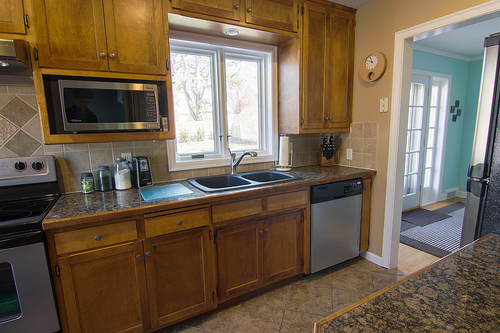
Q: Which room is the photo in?
A: It is at the kitchen.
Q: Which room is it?
A: It is a kitchen.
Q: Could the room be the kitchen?
A: Yes, it is the kitchen.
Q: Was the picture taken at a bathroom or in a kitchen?
A: It was taken at a kitchen.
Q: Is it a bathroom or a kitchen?
A: It is a kitchen.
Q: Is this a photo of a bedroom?
A: No, the picture is showing a kitchen.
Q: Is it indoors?
A: Yes, it is indoors.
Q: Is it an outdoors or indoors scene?
A: It is indoors.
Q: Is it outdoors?
A: No, it is indoors.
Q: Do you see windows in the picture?
A: Yes, there is a window.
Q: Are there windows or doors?
A: Yes, there is a window.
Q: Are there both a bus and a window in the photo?
A: No, there is a window but no buses.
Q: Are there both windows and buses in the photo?
A: No, there is a window but no buses.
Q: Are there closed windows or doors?
A: Yes, there is a closed window.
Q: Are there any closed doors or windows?
A: Yes, there is a closed window.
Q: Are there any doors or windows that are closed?
A: Yes, the window is closed.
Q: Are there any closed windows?
A: Yes, there is a closed window.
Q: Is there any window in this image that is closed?
A: Yes, there is a closed window.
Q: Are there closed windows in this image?
A: Yes, there is a closed window.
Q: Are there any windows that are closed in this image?
A: Yes, there is a closed window.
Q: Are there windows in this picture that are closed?
A: Yes, there is a window that is closed.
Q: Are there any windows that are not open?
A: Yes, there is an closed window.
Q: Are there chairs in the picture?
A: No, there are no chairs.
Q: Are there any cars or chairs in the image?
A: No, there are no chairs or cars.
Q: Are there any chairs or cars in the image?
A: No, there are no chairs or cars.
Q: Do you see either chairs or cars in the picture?
A: No, there are no chairs or cars.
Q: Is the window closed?
A: Yes, the window is closed.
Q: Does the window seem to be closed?
A: Yes, the window is closed.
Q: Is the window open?
A: No, the window is closed.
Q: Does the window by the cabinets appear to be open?
A: No, the window is closed.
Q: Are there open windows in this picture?
A: No, there is a window but it is closed.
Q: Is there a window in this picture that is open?
A: No, there is a window but it is closed.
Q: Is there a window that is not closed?
A: No, there is a window but it is closed.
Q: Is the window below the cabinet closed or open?
A: The window is closed.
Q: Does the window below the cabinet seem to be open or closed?
A: The window is closed.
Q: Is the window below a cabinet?
A: Yes, the window is below a cabinet.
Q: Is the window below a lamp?
A: No, the window is below a cabinet.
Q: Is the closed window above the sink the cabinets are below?
A: Yes, the window is above the sink.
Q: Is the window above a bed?
A: No, the window is above the sink.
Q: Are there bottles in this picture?
A: No, there are no bottles.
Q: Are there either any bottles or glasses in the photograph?
A: No, there are no bottles or glasses.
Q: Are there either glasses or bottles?
A: No, there are no bottles or glasses.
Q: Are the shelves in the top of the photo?
A: Yes, the shelves are in the top of the image.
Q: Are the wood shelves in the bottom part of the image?
A: No, the shelves are in the top of the image.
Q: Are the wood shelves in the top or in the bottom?
A: The shelves are in the top of the image.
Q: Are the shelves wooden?
A: Yes, the shelves are wooden.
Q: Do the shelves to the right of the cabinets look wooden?
A: Yes, the shelves are wooden.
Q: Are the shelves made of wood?
A: Yes, the shelves are made of wood.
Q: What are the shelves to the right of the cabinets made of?
A: The shelves are made of wood.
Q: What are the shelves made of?
A: The shelves are made of wood.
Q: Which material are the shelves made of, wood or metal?
A: The shelves are made of wood.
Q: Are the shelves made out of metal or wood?
A: The shelves are made of wood.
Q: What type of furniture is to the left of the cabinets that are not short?
A: The pieces of furniture are shelves.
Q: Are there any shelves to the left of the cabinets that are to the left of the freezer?
A: Yes, there are shelves to the left of the cabinets.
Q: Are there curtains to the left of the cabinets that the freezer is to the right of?
A: No, there are shelves to the left of the cabinets.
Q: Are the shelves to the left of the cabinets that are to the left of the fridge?
A: Yes, the shelves are to the left of the cabinets.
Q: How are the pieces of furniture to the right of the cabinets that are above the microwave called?
A: The pieces of furniture are shelves.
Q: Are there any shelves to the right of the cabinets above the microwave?
A: Yes, there are shelves to the right of the cabinets.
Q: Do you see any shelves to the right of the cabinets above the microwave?
A: Yes, there are shelves to the right of the cabinets.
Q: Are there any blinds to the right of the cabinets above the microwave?
A: No, there are shelves to the right of the cabinets.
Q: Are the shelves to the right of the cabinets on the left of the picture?
A: Yes, the shelves are to the right of the cabinets.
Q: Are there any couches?
A: No, there are no couches.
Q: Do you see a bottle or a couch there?
A: No, there are no couches or bottles.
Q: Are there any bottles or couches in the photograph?
A: No, there are no couches or bottles.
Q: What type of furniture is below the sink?
A: The pieces of furniture are cabinets.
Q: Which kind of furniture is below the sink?
A: The pieces of furniture are cabinets.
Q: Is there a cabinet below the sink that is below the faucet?
A: Yes, there are cabinets below the sink.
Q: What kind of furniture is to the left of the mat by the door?
A: The pieces of furniture are cabinets.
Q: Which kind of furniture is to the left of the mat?
A: The pieces of furniture are cabinets.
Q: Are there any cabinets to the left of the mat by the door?
A: Yes, there are cabinets to the left of the mat.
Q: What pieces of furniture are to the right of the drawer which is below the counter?
A: The pieces of furniture are cabinets.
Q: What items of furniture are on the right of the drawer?
A: The pieces of furniture are cabinets.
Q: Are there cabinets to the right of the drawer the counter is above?
A: Yes, there are cabinets to the right of the drawer.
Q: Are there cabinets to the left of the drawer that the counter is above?
A: No, the cabinets are to the right of the drawer.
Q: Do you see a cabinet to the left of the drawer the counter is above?
A: No, the cabinets are to the right of the drawer.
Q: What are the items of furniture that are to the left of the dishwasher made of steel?
A: The pieces of furniture are cabinets.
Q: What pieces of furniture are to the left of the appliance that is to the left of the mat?
A: The pieces of furniture are cabinets.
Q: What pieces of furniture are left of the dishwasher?
A: The pieces of furniture are cabinets.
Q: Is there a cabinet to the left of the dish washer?
A: Yes, there are cabinets to the left of the dish washer.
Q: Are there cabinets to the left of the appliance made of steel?
A: Yes, there are cabinets to the left of the dish washer.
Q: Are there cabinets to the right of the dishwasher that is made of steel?
A: No, the cabinets are to the left of the dish washer.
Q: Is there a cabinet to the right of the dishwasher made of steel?
A: No, the cabinets are to the left of the dish washer.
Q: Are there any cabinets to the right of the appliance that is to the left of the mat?
A: No, the cabinets are to the left of the dish washer.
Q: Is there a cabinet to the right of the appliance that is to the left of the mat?
A: No, the cabinets are to the left of the dish washer.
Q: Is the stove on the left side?
A: Yes, the stove is on the left of the image.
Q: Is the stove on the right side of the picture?
A: No, the stove is on the left of the image.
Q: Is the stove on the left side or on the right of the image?
A: The stove is on the left of the image.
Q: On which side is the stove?
A: The stove is on the left of the image.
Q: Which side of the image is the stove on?
A: The stove is on the left of the image.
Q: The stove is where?
A: The stove is in the kitchen.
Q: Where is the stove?
A: The stove is in the kitchen.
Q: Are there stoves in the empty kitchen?
A: Yes, there is a stove in the kitchen.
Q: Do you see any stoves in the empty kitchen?
A: Yes, there is a stove in the kitchen.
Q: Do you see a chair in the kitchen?
A: No, there is a stove in the kitchen.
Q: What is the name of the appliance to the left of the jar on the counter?
A: The appliance is a stove.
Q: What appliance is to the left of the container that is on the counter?
A: The appliance is a stove.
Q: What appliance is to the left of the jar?
A: The appliance is a stove.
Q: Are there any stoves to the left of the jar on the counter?
A: Yes, there is a stove to the left of the jar.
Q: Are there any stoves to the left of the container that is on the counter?
A: Yes, there is a stove to the left of the jar.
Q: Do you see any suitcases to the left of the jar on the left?
A: No, there is a stove to the left of the jar.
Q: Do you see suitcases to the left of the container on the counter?
A: No, there is a stove to the left of the jar.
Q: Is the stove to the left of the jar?
A: Yes, the stove is to the left of the jar.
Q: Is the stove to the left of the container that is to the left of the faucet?
A: Yes, the stove is to the left of the jar.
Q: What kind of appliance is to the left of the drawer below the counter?
A: The appliance is a stove.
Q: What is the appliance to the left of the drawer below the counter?
A: The appliance is a stove.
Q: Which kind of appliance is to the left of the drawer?
A: The appliance is a stove.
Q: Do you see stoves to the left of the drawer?
A: Yes, there is a stove to the left of the drawer.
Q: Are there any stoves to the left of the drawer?
A: Yes, there is a stove to the left of the drawer.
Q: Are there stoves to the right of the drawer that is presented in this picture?
A: No, the stove is to the left of the drawer.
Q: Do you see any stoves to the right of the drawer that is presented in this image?
A: No, the stove is to the left of the drawer.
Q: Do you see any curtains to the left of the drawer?
A: No, there is a stove to the left of the drawer.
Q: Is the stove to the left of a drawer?
A: Yes, the stove is to the left of a drawer.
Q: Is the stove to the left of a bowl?
A: No, the stove is to the left of a drawer.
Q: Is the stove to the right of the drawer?
A: No, the stove is to the left of the drawer.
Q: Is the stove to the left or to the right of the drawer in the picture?
A: The stove is to the left of the drawer.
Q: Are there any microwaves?
A: Yes, there is a microwave.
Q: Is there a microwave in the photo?
A: Yes, there is a microwave.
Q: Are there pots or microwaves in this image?
A: Yes, there is a microwave.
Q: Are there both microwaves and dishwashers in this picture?
A: Yes, there are both a microwave and a dishwasher.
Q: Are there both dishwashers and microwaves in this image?
A: Yes, there are both a microwave and a dishwasher.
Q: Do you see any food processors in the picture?
A: No, there are no food processors.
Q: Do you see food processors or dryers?
A: No, there are no food processors or dryers.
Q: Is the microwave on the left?
A: Yes, the microwave is on the left of the image.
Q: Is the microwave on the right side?
A: No, the microwave is on the left of the image.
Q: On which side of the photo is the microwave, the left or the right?
A: The microwave is on the left of the image.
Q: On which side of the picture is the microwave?
A: The microwave is on the left of the image.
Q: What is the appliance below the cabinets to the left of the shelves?
A: The appliance is a microwave.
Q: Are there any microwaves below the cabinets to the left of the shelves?
A: Yes, there is a microwave below the cabinets.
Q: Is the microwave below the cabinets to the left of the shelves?
A: Yes, the microwave is below the cabinets.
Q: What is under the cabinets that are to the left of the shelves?
A: The microwave is under the cabinets.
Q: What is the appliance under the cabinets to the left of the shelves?
A: The appliance is a microwave.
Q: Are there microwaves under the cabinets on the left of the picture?
A: Yes, there is a microwave under the cabinets.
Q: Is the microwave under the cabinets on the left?
A: Yes, the microwave is under the cabinets.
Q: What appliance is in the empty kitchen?
A: The appliance is a microwave.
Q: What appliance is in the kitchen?
A: The appliance is a microwave.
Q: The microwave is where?
A: The microwave is in the kitchen.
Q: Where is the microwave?
A: The microwave is in the kitchen.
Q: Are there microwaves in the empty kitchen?
A: Yes, there is a microwave in the kitchen.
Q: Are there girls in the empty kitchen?
A: No, there is a microwave in the kitchen.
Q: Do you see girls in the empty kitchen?
A: No, there is a microwave in the kitchen.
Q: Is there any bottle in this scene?
A: No, there are no bottles.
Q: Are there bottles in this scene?
A: No, there are no bottles.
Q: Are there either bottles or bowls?
A: No, there are no bottles or bowls.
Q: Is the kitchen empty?
A: Yes, the kitchen is empty.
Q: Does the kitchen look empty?
A: Yes, the kitchen is empty.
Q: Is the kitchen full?
A: No, the kitchen is empty.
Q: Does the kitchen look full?
A: No, the kitchen is empty.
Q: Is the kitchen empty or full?
A: The kitchen is empty.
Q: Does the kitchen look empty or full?
A: The kitchen is empty.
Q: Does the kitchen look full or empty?
A: The kitchen is empty.